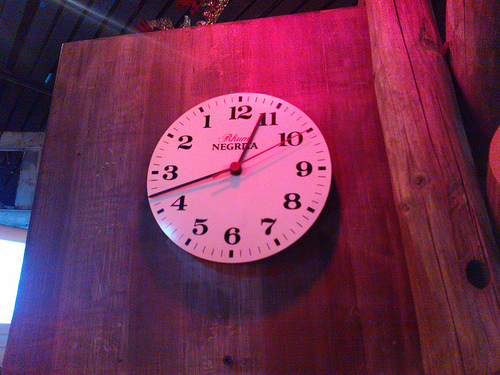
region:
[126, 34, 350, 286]
a clock hanging on a wall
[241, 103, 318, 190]
red second hand on clock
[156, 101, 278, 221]
black time hands on a clock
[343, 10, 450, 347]
a wooden post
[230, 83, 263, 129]
a black number 12 on a clock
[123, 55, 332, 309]
a black and white clock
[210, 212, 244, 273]
a black number 6 on a clock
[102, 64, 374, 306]
a clock with black numbers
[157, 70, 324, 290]
a clock with words printed on it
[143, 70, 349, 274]
a large black and white clock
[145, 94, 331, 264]
large clock on wooden wall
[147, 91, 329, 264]
white clock on wall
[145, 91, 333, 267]
large, white clock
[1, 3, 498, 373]
wooden half wall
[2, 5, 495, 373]
wooden half wall with clock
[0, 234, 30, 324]
open area with sunlight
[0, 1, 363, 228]
wooden ceiling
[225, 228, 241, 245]
number 6 on clock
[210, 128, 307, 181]
red hand of the clock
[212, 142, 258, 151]
the writing NEGRUA on clock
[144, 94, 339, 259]
clock is white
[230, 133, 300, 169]
second hand is red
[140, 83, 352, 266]
clock has numbers in reverse order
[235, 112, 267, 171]
hour hand is black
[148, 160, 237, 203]
minute hand is black and long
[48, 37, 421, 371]
clock on wooden panel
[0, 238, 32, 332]
light is pouring in the background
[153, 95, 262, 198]
clock reads 11:17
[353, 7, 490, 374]
wooden post on side of clock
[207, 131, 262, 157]
clock is from a beer company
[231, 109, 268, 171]
Black short hand on clock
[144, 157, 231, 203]
Black long hand on clock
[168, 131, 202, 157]
Black number two on clock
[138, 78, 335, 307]
Backwards black and white clock on wall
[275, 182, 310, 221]
Black number eight on clock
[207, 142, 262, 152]
Black lettering on clock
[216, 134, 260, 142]
Red lettering on clock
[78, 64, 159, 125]
Brownish wall behind clock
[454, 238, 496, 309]
Black hole in wood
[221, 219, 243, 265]
Black number six on clock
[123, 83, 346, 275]
a round clock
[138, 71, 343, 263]
a clock with black numbers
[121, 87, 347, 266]
a clock with a second hand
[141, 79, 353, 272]
a clock whose numbers are reversed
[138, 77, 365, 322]
a clock whose name says Negria on it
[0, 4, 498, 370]
a clock mounted on a brown wall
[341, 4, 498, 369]
a brown pole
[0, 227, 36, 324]
light is shining through a window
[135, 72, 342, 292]
a backwards clock hanging on a wall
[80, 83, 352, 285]
a white clock with black numbers and a red second hand